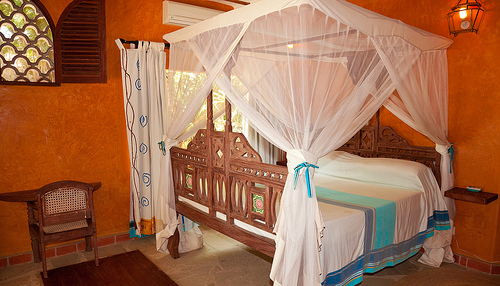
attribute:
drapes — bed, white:
[160, 1, 460, 283]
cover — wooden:
[48, 7, 129, 95]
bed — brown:
[128, 13, 477, 280]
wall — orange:
[0, 0, 235, 264]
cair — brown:
[22, 179, 104, 278]